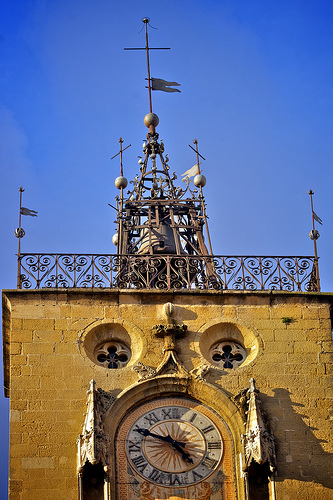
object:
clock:
[125, 405, 222, 489]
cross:
[200, 324, 268, 365]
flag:
[150, 74, 180, 95]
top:
[141, 16, 150, 24]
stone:
[30, 316, 75, 390]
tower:
[115, 104, 218, 288]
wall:
[246, 323, 323, 430]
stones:
[9, 351, 29, 368]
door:
[104, 370, 244, 500]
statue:
[133, 302, 210, 382]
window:
[93, 340, 132, 367]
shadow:
[243, 383, 333, 488]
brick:
[273, 304, 315, 387]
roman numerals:
[124, 401, 225, 489]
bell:
[131, 213, 196, 286]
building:
[0, 5, 333, 500]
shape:
[249, 381, 274, 475]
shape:
[76, 379, 113, 472]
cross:
[124, 16, 173, 77]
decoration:
[149, 302, 190, 378]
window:
[212, 339, 243, 370]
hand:
[133, 425, 187, 448]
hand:
[163, 431, 193, 462]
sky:
[0, 0, 331, 500]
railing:
[14, 247, 320, 293]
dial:
[143, 419, 205, 471]